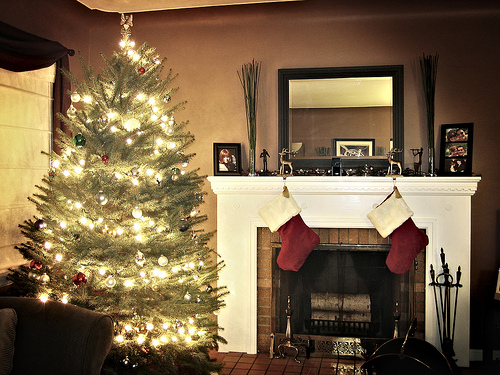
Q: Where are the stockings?
A: On the mantle.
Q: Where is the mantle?
A: Around the fire place.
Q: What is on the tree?
A: Lights.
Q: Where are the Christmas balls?
A: On the tree.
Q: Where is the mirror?
A: Above the mantle.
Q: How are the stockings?
A: Hanging.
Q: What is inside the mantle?
A: Bricks.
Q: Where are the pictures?
A: On the mantle.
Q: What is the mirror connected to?
A: The wall.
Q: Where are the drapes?
A: On the window.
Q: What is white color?
A: Fireplace.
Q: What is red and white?
A: Stockings.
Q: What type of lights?
A: Christmas.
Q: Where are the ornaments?
A: On tree.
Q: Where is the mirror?
A: Above fireplace.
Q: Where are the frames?
A: On mantle.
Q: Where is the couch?
A: By tree.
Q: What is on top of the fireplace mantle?
A: A mirror.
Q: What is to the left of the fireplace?
A: A tall green Christmas tree.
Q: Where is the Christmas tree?
A: In living room.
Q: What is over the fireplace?
A: Brown frame mirror.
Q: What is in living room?
A: White framed fireplace.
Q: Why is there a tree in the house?
A: Christmas.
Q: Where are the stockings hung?
A: Over the chimney.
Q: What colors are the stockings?
A: Red.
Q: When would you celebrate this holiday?
A: December.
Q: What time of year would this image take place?
A: Winter.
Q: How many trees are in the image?
A: One.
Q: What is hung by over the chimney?
A: Stockings.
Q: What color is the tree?
A: Green.